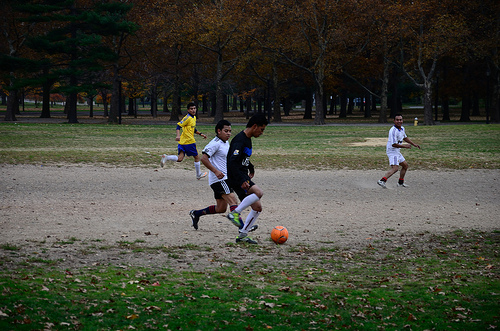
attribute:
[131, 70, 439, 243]
men — playing, going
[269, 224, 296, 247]
ball — soccer, orange, red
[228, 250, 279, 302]
leave — brown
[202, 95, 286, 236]
man — wearing, running, young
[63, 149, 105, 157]
stripe — white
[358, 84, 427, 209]
boy — wearing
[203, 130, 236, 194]
shirt — grey, yellow, white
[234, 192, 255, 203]
sock — white, red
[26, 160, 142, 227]
area — sandy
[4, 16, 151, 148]
tree — tall, many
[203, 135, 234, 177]
clothe — white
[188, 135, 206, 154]
short — blue, black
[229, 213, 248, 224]
boot — green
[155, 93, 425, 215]
people — playing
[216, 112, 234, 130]
hair — black